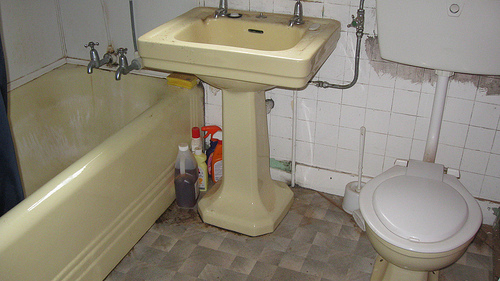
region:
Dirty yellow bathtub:
[20, 79, 127, 188]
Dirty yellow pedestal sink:
[138, 5, 349, 240]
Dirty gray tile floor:
[154, 200, 211, 230]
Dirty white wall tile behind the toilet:
[365, 34, 432, 88]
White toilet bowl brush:
[343, 120, 369, 215]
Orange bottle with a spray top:
[197, 121, 223, 181]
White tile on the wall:
[301, 87, 347, 159]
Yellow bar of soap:
[165, 70, 201, 90]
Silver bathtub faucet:
[78, 35, 139, 86]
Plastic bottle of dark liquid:
[168, 143, 204, 215]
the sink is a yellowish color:
[123, 3, 340, 256]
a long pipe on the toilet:
[418, 58, 453, 165]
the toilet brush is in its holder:
[330, 113, 381, 225]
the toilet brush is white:
[337, 102, 377, 221]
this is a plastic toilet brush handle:
[352, 110, 372, 193]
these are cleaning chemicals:
[159, 108, 230, 210]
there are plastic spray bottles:
[197, 111, 232, 197]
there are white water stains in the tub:
[13, 87, 161, 191]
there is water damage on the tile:
[357, 29, 494, 114]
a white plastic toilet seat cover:
[348, 128, 492, 263]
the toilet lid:
[388, 182, 445, 229]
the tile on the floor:
[251, 239, 298, 279]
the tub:
[46, 130, 88, 158]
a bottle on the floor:
[163, 139, 205, 209]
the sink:
[206, 24, 279, 56]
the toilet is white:
[350, 177, 485, 269]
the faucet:
[283, 0, 308, 25]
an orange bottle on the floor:
[203, 123, 230, 173]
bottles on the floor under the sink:
[171, 116, 221, 207]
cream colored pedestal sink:
[131, 17, 325, 232]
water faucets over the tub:
[71, 40, 137, 85]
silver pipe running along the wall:
[342, 2, 367, 95]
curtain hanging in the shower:
[1, 41, 30, 202]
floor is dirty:
[165, 201, 204, 241]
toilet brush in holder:
[346, 105, 371, 222]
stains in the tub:
[14, 104, 90, 155]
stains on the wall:
[93, 4, 125, 51]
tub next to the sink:
[10, 33, 228, 250]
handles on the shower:
[76, 35, 133, 92]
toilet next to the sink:
[345, 99, 473, 279]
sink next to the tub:
[149, 5, 345, 253]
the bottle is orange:
[196, 116, 240, 182]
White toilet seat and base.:
[356, 158, 482, 280]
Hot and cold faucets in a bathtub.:
[85, 40, 130, 81]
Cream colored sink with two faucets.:
[134, 6, 340, 237]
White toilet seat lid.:
[372, 174, 469, 244]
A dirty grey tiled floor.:
[105, 187, 494, 279]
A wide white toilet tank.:
[374, 1, 499, 73]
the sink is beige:
[136, 4, 337, 86]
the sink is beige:
[194, 71, 292, 233]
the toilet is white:
[355, 155, 481, 278]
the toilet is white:
[375, 0, 497, 160]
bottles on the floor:
[175, 124, 222, 211]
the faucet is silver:
[82, 38, 111, 74]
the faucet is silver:
[111, 51, 142, 78]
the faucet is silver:
[211, 1, 226, 14]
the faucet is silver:
[288, 3, 301, 24]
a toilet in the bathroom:
[349, 163, 451, 267]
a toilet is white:
[343, 157, 499, 278]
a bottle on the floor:
[178, 140, 201, 215]